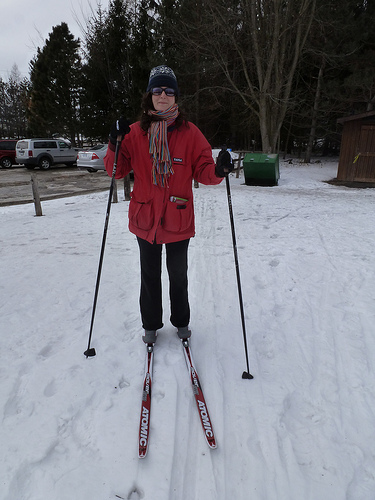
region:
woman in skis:
[69, 59, 257, 454]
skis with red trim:
[125, 312, 223, 474]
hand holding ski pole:
[212, 144, 259, 383]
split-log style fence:
[1, 170, 121, 209]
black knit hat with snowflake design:
[141, 62, 179, 91]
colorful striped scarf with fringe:
[133, 98, 195, 189]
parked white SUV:
[9, 134, 86, 173]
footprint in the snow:
[45, 358, 87, 401]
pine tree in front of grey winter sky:
[25, 17, 82, 148]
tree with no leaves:
[203, 1, 320, 164]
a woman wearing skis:
[65, 35, 293, 488]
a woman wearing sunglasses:
[135, 57, 188, 132]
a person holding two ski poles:
[83, 107, 280, 399]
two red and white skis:
[129, 317, 240, 485]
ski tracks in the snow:
[169, 368, 366, 497]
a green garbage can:
[235, 148, 292, 191]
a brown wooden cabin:
[329, 108, 374, 210]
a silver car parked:
[72, 144, 111, 176]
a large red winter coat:
[94, 99, 246, 260]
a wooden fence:
[5, 161, 110, 224]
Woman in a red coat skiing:
[67, 54, 295, 462]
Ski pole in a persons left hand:
[212, 153, 263, 397]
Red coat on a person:
[100, 122, 224, 240]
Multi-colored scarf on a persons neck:
[143, 110, 182, 183]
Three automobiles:
[2, 127, 116, 174]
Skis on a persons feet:
[128, 325, 234, 471]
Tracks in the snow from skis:
[163, 418, 197, 493]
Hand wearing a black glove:
[212, 146, 232, 181]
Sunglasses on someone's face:
[148, 85, 181, 100]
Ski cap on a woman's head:
[146, 67, 181, 85]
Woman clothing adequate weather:
[100, 59, 230, 259]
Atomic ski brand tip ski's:
[132, 312, 221, 463]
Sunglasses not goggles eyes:
[138, 62, 185, 116]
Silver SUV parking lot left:
[4, 133, 87, 179]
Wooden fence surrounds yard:
[3, 172, 102, 218]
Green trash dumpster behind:
[235, 145, 310, 198]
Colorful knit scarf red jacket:
[130, 106, 195, 205]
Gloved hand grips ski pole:
[211, 143, 259, 391]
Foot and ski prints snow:
[23, 212, 362, 306]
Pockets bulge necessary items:
[125, 189, 209, 244]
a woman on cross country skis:
[56, 47, 280, 458]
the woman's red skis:
[119, 332, 247, 491]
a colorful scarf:
[138, 104, 188, 178]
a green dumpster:
[239, 149, 292, 198]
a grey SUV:
[15, 134, 81, 174]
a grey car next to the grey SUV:
[73, 137, 112, 173]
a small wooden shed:
[330, 99, 371, 193]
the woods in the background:
[6, 5, 366, 166]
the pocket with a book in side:
[163, 191, 201, 227]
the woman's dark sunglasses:
[146, 84, 181, 100]